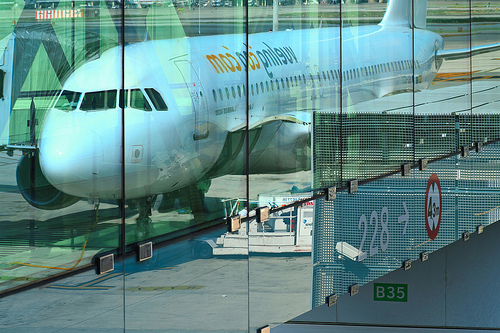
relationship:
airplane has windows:
[36, 0, 500, 240] [208, 85, 218, 107]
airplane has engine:
[36, 0, 500, 240] [14, 150, 82, 214]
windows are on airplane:
[208, 85, 218, 107] [36, 0, 500, 240]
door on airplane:
[173, 53, 209, 141] [36, 0, 500, 240]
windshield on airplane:
[79, 86, 119, 116] [36, 0, 500, 240]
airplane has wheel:
[36, 0, 500, 240] [131, 223, 154, 241]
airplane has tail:
[36, 0, 500, 240] [379, 0, 500, 65]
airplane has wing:
[36, 0, 500, 240] [242, 110, 315, 174]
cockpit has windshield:
[38, 37, 210, 198] [79, 86, 119, 116]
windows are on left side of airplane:
[208, 85, 218, 107] [36, 0, 500, 240]